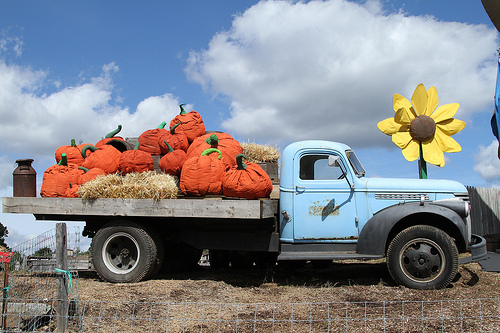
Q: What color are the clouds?
A: White.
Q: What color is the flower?
A: Yellow and brown.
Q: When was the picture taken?
A: Daytime.